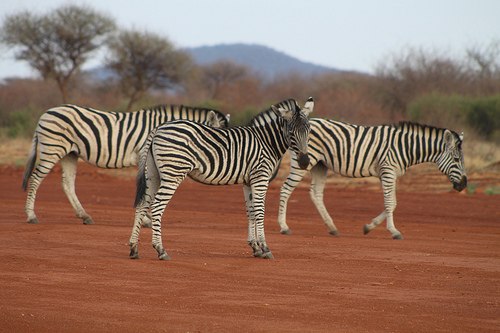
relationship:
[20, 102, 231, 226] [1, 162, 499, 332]
zebra standing on ground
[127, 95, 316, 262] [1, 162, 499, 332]
zebra standing on ground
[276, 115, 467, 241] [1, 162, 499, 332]
zebra standing on ground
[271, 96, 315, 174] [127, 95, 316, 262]
head of zebra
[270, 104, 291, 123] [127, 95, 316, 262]
ear of zebra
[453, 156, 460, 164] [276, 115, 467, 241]
eye of zebra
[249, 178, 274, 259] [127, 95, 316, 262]
front leg of zebra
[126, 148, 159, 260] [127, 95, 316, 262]
hind leg of zebra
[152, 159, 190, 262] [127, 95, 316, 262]
hind leg of zebra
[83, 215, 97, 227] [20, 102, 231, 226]
hoof of zebra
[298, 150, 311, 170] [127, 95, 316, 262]
snout of zebra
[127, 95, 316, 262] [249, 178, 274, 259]
zebra has front leg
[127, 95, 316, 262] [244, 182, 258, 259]
zebra has front leg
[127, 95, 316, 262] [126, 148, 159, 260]
zebra has hind leg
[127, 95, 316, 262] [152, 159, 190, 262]
zebra has hind leg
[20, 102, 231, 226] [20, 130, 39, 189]
zebra has tail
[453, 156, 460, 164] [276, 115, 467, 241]
eye on zebra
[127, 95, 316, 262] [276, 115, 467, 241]
zebra standing near zebra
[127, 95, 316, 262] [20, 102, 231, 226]
zebra standing near zebra